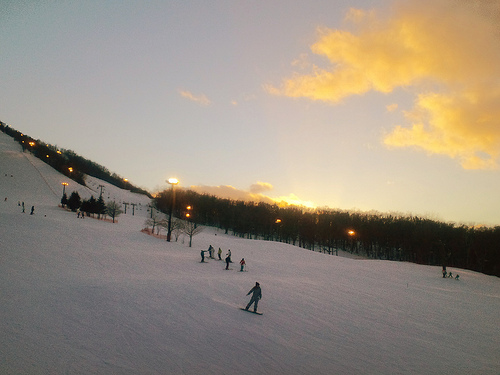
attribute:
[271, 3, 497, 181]
cloud — yellow, large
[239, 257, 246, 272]
skier — group, numerous, down hill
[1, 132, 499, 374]
slope — snowy, white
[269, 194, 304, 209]
sun — setting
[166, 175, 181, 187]
light — on, lit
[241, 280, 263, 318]
boarder — boarding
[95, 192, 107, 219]
tree — green, numberous, small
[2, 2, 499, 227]
sky — blue, cloudy